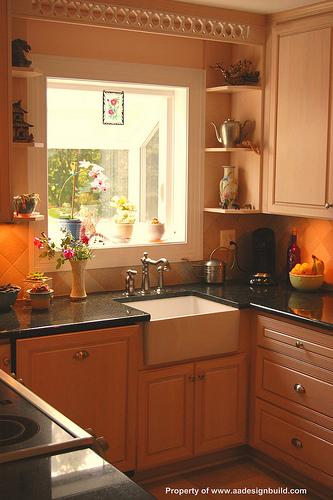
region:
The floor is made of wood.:
[137, 454, 326, 499]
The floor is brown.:
[135, 454, 325, 499]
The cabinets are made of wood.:
[0, 309, 332, 499]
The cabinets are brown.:
[0, 307, 332, 499]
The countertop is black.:
[1, 271, 332, 343]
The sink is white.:
[119, 293, 237, 367]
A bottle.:
[285, 225, 299, 286]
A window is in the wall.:
[26, 54, 202, 273]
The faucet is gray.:
[122, 251, 172, 294]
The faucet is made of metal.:
[124, 251, 171, 294]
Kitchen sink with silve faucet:
[121, 252, 233, 361]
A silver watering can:
[179, 245, 237, 286]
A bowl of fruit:
[286, 255, 326, 288]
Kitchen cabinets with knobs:
[132, 351, 244, 467]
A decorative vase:
[218, 163, 238, 207]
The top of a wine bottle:
[287, 223, 299, 266]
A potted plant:
[12, 192, 40, 216]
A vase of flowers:
[60, 226, 95, 301]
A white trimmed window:
[34, 69, 196, 256]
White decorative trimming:
[34, 2, 258, 47]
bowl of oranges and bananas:
[285, 252, 325, 291]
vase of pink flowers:
[30, 227, 90, 299]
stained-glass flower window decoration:
[99, 87, 125, 127]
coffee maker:
[225, 227, 275, 285]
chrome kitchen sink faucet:
[120, 250, 171, 297]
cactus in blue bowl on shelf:
[9, 190, 43, 220]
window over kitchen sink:
[28, 53, 202, 262]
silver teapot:
[206, 116, 251, 151]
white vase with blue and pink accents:
[216, 164, 239, 212]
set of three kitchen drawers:
[254, 308, 331, 486]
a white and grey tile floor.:
[182, 467, 278, 498]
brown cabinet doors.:
[135, 350, 255, 477]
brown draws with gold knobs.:
[247, 303, 330, 492]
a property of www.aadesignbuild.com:
[159, 481, 315, 498]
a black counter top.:
[230, 279, 327, 311]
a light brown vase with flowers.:
[41, 203, 109, 298]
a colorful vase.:
[210, 154, 245, 209]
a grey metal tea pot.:
[192, 107, 267, 150]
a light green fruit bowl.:
[272, 242, 328, 299]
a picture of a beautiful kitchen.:
[0, 67, 330, 494]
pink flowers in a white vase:
[33, 230, 109, 295]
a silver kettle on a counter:
[181, 245, 235, 284]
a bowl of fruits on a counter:
[288, 255, 325, 291]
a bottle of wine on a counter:
[287, 226, 301, 290]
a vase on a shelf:
[220, 164, 240, 209]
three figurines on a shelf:
[219, 199, 254, 209]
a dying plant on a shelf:
[14, 192, 42, 217]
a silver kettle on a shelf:
[208, 115, 254, 149]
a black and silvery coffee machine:
[247, 226, 277, 289]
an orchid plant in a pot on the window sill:
[60, 158, 109, 246]